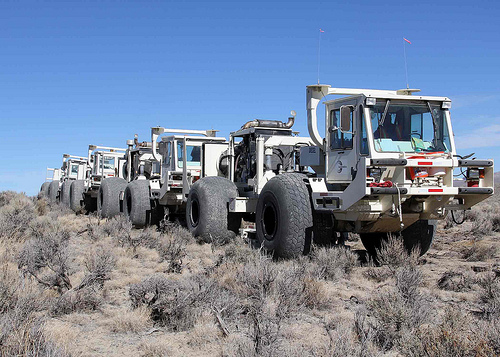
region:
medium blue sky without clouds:
[69, 30, 248, 84]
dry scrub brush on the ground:
[14, 194, 154, 331]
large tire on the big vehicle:
[244, 165, 318, 255]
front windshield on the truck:
[369, 102, 447, 156]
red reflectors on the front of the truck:
[406, 157, 448, 194]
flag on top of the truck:
[397, 18, 422, 90]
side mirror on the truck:
[316, 100, 360, 150]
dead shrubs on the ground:
[137, 269, 216, 340]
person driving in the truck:
[376, 109, 407, 149]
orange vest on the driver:
[379, 123, 405, 139]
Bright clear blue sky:
[0, 0, 497, 192]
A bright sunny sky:
[5, 1, 499, 191]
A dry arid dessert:
[2, 190, 497, 355]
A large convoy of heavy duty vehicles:
[42, 88, 493, 258]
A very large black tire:
[254, 173, 311, 262]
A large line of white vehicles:
[40, 88, 460, 259]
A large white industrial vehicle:
[190, 84, 486, 266]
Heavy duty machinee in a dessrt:
[182, 86, 491, 262]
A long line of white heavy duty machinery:
[37, 85, 491, 262]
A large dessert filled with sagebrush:
[1, 191, 498, 353]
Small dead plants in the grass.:
[50, 270, 102, 307]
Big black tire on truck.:
[258, 170, 308, 252]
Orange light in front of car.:
[413, 157, 443, 167]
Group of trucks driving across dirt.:
[61, 81, 454, 243]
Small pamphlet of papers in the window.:
[408, 132, 426, 149]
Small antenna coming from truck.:
[311, 44, 324, 89]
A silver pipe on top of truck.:
[241, 105, 301, 129]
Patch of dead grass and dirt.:
[69, 313, 127, 350]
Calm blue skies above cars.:
[17, 53, 148, 105]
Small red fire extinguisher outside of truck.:
[464, 158, 486, 190]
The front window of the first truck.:
[361, 108, 451, 154]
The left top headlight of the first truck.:
[363, 97, 385, 110]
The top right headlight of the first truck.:
[440, 100, 450, 107]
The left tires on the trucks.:
[30, 175, 313, 255]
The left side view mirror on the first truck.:
[336, 105, 353, 131]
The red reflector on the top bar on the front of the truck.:
[413, 157, 435, 166]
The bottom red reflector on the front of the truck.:
[427, 185, 447, 193]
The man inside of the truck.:
[378, 111, 405, 136]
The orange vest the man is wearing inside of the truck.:
[382, 125, 401, 135]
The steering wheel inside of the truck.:
[398, 128, 430, 140]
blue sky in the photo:
[38, 23, 176, 103]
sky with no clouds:
[41, 59, 159, 111]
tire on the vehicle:
[246, 166, 336, 261]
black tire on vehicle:
[232, 168, 329, 260]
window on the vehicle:
[356, 98, 463, 168]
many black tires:
[44, 146, 311, 288]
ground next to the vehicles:
[126, 245, 222, 323]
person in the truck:
[368, 110, 413, 144]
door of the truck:
[305, 104, 366, 187]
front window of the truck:
[356, 100, 458, 161]